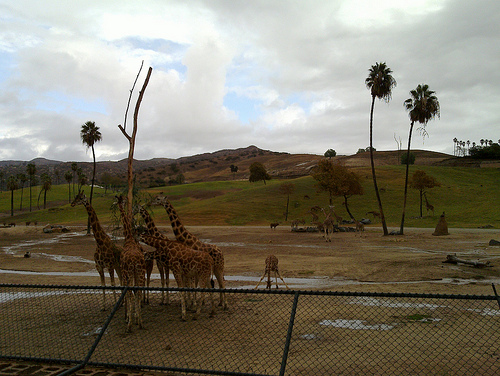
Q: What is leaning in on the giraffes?
A: A fence.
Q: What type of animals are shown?
A: Giraffes.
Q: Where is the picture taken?
A: A zoo.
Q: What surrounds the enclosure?
A: Metal fence.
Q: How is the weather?
A: Overcast.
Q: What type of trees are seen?
A: Palm.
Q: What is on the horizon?
A: Hills.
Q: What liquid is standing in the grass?
A: Water.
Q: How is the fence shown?
A: Down.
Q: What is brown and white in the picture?
A: Giraffes.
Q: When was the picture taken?
A: Daytime.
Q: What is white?
A: Clouds.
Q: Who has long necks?
A: Giraffe.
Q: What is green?
A: Grass.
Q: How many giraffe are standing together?
A: Four.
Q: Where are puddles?
A: On the ground.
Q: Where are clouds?
A: In the sky.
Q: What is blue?
A: Sky.